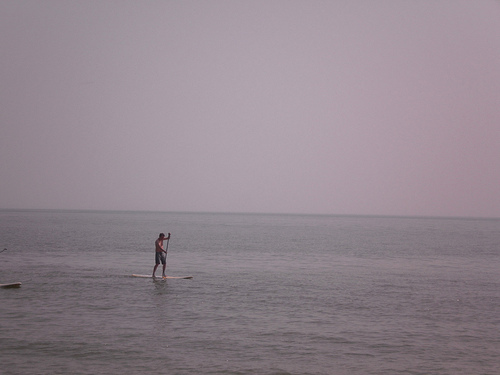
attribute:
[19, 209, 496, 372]
ocean — vast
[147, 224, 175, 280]
man — paddleing, wearing short, wearing shorts, paddleboarding, paddling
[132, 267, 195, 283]
board — white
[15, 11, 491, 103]
sky — clear, gray, grey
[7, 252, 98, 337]
water — murky, dark, calm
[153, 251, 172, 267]
shorts — grey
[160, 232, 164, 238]
hair — short, brown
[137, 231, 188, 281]
male — paddle boarding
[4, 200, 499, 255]
horizon — vast